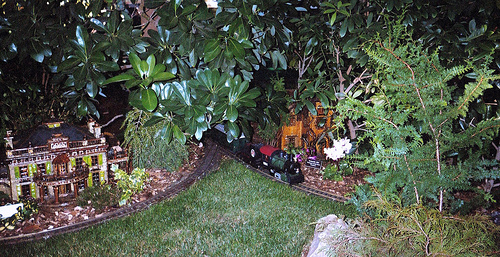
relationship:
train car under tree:
[247, 139, 298, 182] [12, 4, 249, 169]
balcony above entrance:
[28, 149, 133, 207] [22, 139, 109, 210]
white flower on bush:
[322, 135, 356, 164] [338, 33, 498, 208]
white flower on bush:
[322, 135, 356, 164] [113, 0, 250, 133]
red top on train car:
[253, 139, 279, 157] [247, 139, 298, 182]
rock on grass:
[296, 211, 371, 255] [1, 147, 376, 254]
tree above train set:
[1, 0, 499, 145] [1, 97, 358, 245]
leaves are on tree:
[132, 53, 164, 103] [9, 2, 266, 138]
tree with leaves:
[353, 50, 490, 180] [130, 41, 229, 86]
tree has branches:
[0, 7, 354, 151] [54, 32, 434, 147]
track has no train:
[3, 139, 218, 246] [108, 175, 190, 215]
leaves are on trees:
[1, 4, 497, 195] [11, 3, 497, 193]